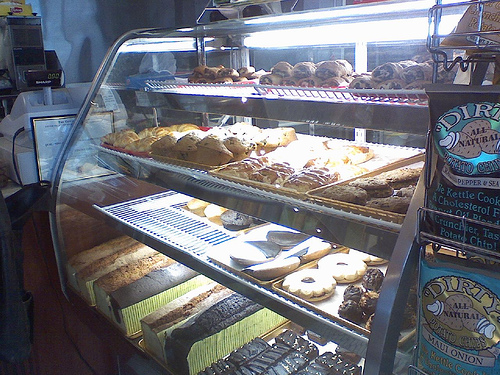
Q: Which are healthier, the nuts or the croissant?
A: The nuts are healthier than the croissant.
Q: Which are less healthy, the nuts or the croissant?
A: The croissant are less healthy than the nuts.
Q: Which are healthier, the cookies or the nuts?
A: The nuts are healthier than the cookies.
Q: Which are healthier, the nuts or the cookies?
A: The nuts are healthier than the cookies.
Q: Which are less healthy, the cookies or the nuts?
A: The cookies are less healthy than the nuts.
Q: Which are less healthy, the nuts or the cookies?
A: The cookies are less healthy than the nuts.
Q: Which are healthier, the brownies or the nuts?
A: The nuts are healthier than the brownies.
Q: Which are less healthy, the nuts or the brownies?
A: The brownies are less healthy than the nuts.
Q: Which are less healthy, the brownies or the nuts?
A: The brownies are less healthy than the nuts.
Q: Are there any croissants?
A: Yes, there is a croissant.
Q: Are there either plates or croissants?
A: Yes, there is a croissant.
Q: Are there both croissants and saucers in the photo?
A: No, there is a croissant but no saucers.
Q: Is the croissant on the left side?
A: Yes, the croissant is on the left of the image.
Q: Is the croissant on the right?
A: No, the croissant is on the left of the image.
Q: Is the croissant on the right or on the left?
A: The croissant is on the left of the image.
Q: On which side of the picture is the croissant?
A: The croissant is on the left of the image.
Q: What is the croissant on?
A: The croissant is on the tray.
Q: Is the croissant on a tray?
A: Yes, the croissant is on a tray.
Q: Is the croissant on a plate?
A: No, the croissant is on a tray.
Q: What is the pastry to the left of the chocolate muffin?
A: The pastry is a croissant.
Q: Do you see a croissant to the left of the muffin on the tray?
A: Yes, there is a croissant to the left of the muffin.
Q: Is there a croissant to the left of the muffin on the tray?
A: Yes, there is a croissant to the left of the muffin.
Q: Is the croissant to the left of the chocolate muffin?
A: Yes, the croissant is to the left of the muffin.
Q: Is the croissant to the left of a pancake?
A: No, the croissant is to the left of the muffin.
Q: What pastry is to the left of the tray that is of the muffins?
A: The pastry is a croissant.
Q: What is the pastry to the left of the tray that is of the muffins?
A: The pastry is a croissant.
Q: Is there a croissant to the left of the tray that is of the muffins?
A: Yes, there is a croissant to the left of the tray.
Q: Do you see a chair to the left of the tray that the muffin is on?
A: No, there is a croissant to the left of the tray.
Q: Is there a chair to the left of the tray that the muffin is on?
A: No, there is a croissant to the left of the tray.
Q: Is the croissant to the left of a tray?
A: Yes, the croissant is to the left of a tray.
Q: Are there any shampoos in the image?
A: No, there are no shampoos.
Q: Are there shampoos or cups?
A: No, there are no shampoos or cups.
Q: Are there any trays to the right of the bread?
A: Yes, there is a tray to the right of the bread.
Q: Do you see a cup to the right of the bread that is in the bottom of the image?
A: No, there is a tray to the right of the bread.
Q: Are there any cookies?
A: Yes, there are cookies.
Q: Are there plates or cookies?
A: Yes, there are cookies.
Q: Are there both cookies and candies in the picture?
A: No, there are cookies but no candies.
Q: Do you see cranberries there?
A: No, there are no cranberries.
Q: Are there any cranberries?
A: No, there are no cranberries.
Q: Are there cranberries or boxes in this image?
A: No, there are no cranberries or boxes.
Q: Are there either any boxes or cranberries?
A: No, there are no cranberries or boxes.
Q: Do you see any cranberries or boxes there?
A: No, there are no cranberries or boxes.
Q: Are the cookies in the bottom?
A: Yes, the cookies are in the bottom of the image.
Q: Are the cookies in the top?
A: No, the cookies are in the bottom of the image.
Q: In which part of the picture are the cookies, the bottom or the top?
A: The cookies are in the bottom of the image.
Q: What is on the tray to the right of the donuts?
A: The cookies are on the tray.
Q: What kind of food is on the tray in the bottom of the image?
A: The food is cookies.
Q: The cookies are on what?
A: The cookies are on the tray.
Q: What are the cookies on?
A: The cookies are on the tray.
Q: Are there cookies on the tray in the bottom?
A: Yes, there are cookies on the tray.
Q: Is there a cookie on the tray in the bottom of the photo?
A: Yes, there are cookies on the tray.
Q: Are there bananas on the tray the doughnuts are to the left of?
A: No, there are cookies on the tray.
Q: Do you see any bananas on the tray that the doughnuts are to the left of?
A: No, there are cookies on the tray.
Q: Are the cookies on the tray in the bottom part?
A: Yes, the cookies are on the tray.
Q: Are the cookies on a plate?
A: No, the cookies are on the tray.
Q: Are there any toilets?
A: No, there are no toilets.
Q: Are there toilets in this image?
A: No, there are no toilets.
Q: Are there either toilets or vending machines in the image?
A: No, there are no toilets or vending machines.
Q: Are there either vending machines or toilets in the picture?
A: No, there are no toilets or vending machines.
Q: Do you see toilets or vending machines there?
A: No, there are no toilets or vending machines.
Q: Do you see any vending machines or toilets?
A: No, there are no toilets or vending machines.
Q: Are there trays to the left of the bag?
A: Yes, there is a tray to the left of the bag.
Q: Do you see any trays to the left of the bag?
A: Yes, there is a tray to the left of the bag.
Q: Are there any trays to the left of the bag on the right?
A: Yes, there is a tray to the left of the bag.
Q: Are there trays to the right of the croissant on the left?
A: Yes, there is a tray to the right of the croissant.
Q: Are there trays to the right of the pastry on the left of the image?
A: Yes, there is a tray to the right of the croissant.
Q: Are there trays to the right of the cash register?
A: Yes, there is a tray to the right of the cash register.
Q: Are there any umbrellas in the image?
A: No, there are no umbrellas.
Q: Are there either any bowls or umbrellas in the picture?
A: No, there are no umbrellas or bowls.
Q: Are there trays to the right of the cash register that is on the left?
A: Yes, there is a tray to the right of the cash register.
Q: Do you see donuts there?
A: Yes, there are donuts.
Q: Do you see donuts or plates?
A: Yes, there are donuts.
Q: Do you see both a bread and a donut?
A: Yes, there are both a donut and a bread.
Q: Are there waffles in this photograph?
A: No, there are no waffles.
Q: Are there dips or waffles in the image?
A: No, there are no waffles or dips.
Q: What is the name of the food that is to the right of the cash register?
A: The food is donuts.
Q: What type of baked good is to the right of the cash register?
A: The food is donuts.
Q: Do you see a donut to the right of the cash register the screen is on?
A: Yes, there are donuts to the right of the cash register.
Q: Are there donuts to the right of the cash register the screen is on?
A: Yes, there are donuts to the right of the cash register.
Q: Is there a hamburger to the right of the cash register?
A: No, there are donuts to the right of the cash register.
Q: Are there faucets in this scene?
A: No, there are no faucets.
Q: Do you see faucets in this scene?
A: No, there are no faucets.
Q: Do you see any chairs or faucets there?
A: No, there are no faucets or chairs.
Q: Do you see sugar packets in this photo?
A: No, there are no sugar packets.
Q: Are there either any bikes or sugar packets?
A: No, there are no sugar packets or bikes.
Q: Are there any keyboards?
A: No, there are no keyboards.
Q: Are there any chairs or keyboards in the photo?
A: No, there are no keyboards or chairs.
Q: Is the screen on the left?
A: Yes, the screen is on the left of the image.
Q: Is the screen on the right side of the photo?
A: No, the screen is on the left of the image.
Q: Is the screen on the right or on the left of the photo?
A: The screen is on the left of the image.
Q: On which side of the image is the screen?
A: The screen is on the left of the image.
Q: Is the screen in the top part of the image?
A: Yes, the screen is in the top of the image.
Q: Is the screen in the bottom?
A: No, the screen is in the top of the image.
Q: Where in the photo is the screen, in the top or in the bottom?
A: The screen is in the top of the image.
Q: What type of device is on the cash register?
A: The device is a screen.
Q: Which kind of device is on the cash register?
A: The device is a screen.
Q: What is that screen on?
A: The screen is on the cash register.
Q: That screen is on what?
A: The screen is on the cash register.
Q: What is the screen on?
A: The screen is on the cash register.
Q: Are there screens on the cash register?
A: Yes, there is a screen on the cash register.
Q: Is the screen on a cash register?
A: Yes, the screen is on a cash register.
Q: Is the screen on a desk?
A: No, the screen is on a cash register.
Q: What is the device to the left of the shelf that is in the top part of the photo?
A: The device is a screen.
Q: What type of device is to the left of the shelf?
A: The device is a screen.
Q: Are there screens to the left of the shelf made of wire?
A: Yes, there is a screen to the left of the shelf.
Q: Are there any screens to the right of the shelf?
A: No, the screen is to the left of the shelf.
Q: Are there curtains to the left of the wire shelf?
A: No, there is a screen to the left of the shelf.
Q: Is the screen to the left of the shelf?
A: Yes, the screen is to the left of the shelf.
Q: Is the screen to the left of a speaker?
A: No, the screen is to the left of the shelf.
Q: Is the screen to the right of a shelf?
A: No, the screen is to the left of a shelf.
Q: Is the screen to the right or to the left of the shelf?
A: The screen is to the left of the shelf.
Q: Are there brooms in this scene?
A: No, there are no brooms.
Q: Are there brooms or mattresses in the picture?
A: No, there are no brooms or mattresses.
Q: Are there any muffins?
A: Yes, there is a muffin.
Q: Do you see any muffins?
A: Yes, there is a muffin.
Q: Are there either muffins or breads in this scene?
A: Yes, there is a muffin.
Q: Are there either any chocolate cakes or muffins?
A: Yes, there is a chocolate muffin.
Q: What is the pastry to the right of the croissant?
A: The pastry is a muffin.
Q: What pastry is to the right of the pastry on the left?
A: The pastry is a muffin.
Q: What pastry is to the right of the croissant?
A: The pastry is a muffin.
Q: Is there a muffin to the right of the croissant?
A: Yes, there is a muffin to the right of the croissant.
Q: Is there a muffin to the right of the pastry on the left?
A: Yes, there is a muffin to the right of the croissant.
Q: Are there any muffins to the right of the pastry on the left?
A: Yes, there is a muffin to the right of the croissant.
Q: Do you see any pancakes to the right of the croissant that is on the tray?
A: No, there is a muffin to the right of the croissant.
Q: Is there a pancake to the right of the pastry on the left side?
A: No, there is a muffin to the right of the croissant.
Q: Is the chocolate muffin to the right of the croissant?
A: Yes, the muffin is to the right of the croissant.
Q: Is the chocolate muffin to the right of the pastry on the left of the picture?
A: Yes, the muffin is to the right of the croissant.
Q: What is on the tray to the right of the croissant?
A: The muffin is on the tray.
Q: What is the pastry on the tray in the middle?
A: The pastry is a muffin.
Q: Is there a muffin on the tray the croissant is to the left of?
A: Yes, there is a muffin on the tray.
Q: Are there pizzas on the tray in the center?
A: No, there is a muffin on the tray.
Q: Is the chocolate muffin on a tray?
A: Yes, the muffin is on a tray.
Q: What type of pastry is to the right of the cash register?
A: The pastry is a muffin.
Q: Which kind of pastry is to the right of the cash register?
A: The pastry is a muffin.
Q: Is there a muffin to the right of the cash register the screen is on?
A: Yes, there is a muffin to the right of the cash register.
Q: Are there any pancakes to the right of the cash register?
A: No, there is a muffin to the right of the cash register.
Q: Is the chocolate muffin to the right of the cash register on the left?
A: Yes, the muffin is to the right of the cash register.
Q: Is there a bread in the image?
A: Yes, there is a bread.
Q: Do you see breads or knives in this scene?
A: Yes, there is a bread.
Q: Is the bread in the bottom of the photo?
A: Yes, the bread is in the bottom of the image.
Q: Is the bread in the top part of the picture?
A: No, the bread is in the bottom of the image.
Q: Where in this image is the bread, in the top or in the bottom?
A: The bread is in the bottom of the image.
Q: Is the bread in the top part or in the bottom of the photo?
A: The bread is in the bottom of the image.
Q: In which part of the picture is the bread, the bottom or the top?
A: The bread is in the bottom of the image.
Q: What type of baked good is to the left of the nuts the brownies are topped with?
A: The food is a bread.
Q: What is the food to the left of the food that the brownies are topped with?
A: The food is a bread.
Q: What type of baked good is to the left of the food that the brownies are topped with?
A: The food is a bread.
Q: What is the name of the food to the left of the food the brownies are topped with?
A: The food is a bread.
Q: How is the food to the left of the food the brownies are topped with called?
A: The food is a bread.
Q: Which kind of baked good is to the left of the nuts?
A: The food is a bread.